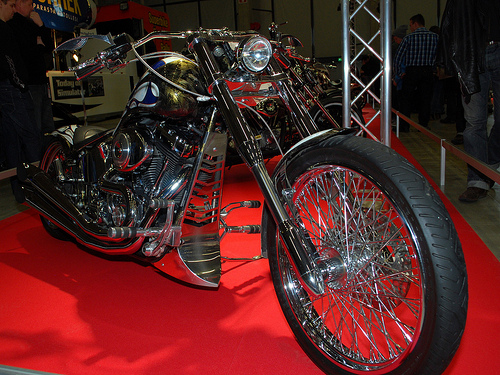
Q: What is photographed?
A: A motorcycle.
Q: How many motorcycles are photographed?
A: One.